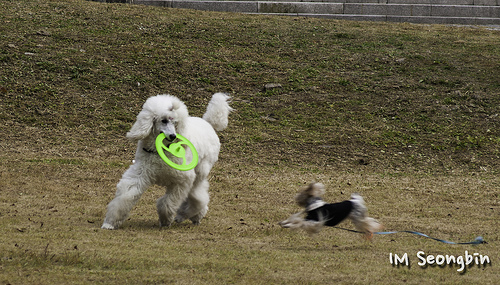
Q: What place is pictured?
A: It is a park.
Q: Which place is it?
A: It is a park.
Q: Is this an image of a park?
A: Yes, it is showing a park.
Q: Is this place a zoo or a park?
A: It is a park.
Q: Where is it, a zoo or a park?
A: It is a park.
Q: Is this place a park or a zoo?
A: It is a park.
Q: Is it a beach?
A: No, it is a park.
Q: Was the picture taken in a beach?
A: No, the picture was taken in a park.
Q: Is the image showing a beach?
A: No, the picture is showing a park.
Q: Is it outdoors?
A: Yes, it is outdoors.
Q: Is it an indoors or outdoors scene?
A: It is outdoors.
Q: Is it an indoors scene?
A: No, it is outdoors.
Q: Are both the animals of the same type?
A: Yes, all the animals are dogs.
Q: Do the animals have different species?
A: No, all the animals are dogs.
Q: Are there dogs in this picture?
A: Yes, there is a dog.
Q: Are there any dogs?
A: Yes, there is a dog.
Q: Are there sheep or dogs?
A: Yes, there is a dog.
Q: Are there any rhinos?
A: No, there are no rhinos.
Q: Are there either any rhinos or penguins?
A: No, there are no rhinos or penguins.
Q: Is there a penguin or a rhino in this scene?
A: No, there are no rhinos or penguins.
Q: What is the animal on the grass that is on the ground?
A: The animal is a dog.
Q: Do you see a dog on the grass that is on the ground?
A: Yes, there is a dog on the grass.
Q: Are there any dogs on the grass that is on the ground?
A: Yes, there is a dog on the grass.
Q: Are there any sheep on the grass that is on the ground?
A: No, there is a dog on the grass.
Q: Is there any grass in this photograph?
A: Yes, there is grass.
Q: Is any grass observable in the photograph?
A: Yes, there is grass.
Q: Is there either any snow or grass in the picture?
A: Yes, there is grass.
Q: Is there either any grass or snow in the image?
A: Yes, there is grass.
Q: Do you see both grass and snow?
A: No, there is grass but no snow.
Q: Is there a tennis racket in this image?
A: No, there are no rackets.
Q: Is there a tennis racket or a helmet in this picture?
A: No, there are no rackets or helmets.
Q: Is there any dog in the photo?
A: Yes, there is a dog.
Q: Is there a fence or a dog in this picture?
A: Yes, there is a dog.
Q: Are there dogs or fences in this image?
A: Yes, there is a dog.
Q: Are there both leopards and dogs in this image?
A: No, there is a dog but no leopards.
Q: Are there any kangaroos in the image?
A: No, there are no kangaroos.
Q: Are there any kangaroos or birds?
A: No, there are no kangaroos or birds.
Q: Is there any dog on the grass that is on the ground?
A: Yes, there is a dog on the grass.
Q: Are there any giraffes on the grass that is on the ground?
A: No, there is a dog on the grass.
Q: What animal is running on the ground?
A: The dog is running on the ground.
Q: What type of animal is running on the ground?
A: The animal is a dog.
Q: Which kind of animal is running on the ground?
A: The animal is a dog.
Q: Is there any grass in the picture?
A: Yes, there is grass.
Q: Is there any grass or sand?
A: Yes, there is grass.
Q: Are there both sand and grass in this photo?
A: No, there is grass but no sand.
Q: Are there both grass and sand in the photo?
A: No, there is grass but no sand.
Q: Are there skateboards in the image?
A: No, there are no skateboards.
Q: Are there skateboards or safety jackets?
A: No, there are no skateboards or safety jackets.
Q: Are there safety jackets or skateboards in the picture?
A: No, there are no skateboards or safety jackets.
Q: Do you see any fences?
A: No, there are no fences.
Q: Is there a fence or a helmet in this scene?
A: No, there are no fences or helmets.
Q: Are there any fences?
A: No, there are no fences.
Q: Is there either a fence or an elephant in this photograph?
A: No, there are no fences or elephants.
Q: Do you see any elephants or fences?
A: No, there are no fences or elephants.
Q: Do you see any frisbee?
A: Yes, there is a frisbee.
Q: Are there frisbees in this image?
A: Yes, there is a frisbee.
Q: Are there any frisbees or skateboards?
A: Yes, there is a frisbee.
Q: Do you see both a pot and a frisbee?
A: No, there is a frisbee but no pots.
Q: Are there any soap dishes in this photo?
A: No, there are no soap dishes.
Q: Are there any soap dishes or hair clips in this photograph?
A: No, there are no soap dishes or hair clips.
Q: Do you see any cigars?
A: No, there are no cigars.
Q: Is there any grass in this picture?
A: Yes, there is grass.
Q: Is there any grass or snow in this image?
A: Yes, there is grass.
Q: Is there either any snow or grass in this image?
A: Yes, there is grass.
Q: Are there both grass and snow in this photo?
A: No, there is grass but no snow.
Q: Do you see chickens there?
A: No, there are no chickens.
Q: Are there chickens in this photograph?
A: No, there are no chickens.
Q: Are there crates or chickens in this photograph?
A: No, there are no chickens or crates.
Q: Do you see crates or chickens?
A: No, there are no chickens or crates.